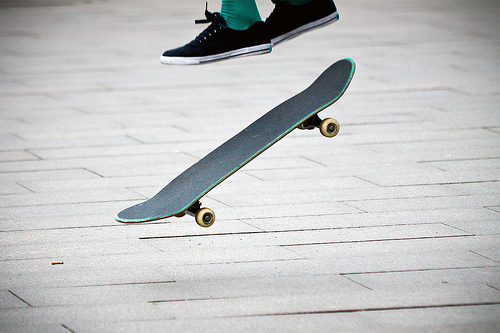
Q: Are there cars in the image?
A: No, there are no cars.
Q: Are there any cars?
A: No, there are no cars.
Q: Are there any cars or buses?
A: No, there are no cars or buses.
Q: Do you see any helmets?
A: No, there are no helmets.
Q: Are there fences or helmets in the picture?
A: No, there are no helmets or fences.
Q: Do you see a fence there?
A: No, there are no fences.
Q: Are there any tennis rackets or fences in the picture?
A: No, there are no fences or tennis rackets.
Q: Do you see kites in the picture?
A: No, there are no kites.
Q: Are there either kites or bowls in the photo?
A: No, there are no kites or bowls.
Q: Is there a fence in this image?
A: No, there are no fences.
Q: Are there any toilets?
A: No, there are no toilets.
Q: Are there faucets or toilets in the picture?
A: No, there are no toilets or faucets.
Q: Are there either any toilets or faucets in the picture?
A: No, there are no toilets or faucets.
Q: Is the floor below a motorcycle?
A: No, the floor is below the skateboard.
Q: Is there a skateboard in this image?
A: Yes, there is a skateboard.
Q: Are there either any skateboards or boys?
A: Yes, there is a skateboard.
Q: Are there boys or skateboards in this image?
A: Yes, there is a skateboard.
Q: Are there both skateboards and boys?
A: No, there is a skateboard but no boys.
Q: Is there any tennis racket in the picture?
A: No, there are no rackets.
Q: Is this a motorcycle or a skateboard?
A: This is a skateboard.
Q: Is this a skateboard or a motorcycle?
A: This is a skateboard.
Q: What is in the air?
A: The skateboard is in the air.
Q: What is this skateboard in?
A: The skateboard is in the air.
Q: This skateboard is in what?
A: The skateboard is in the air.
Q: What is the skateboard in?
A: The skateboard is in the air.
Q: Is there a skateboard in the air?
A: Yes, there is a skateboard in the air.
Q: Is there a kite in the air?
A: No, there is a skateboard in the air.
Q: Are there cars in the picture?
A: No, there are no cars.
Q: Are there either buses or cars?
A: No, there are no cars or buses.